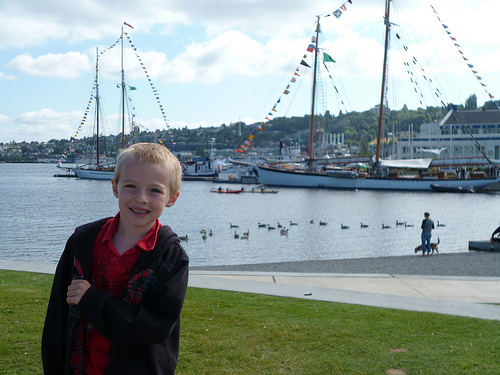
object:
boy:
[41, 142, 190, 375]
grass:
[0, 267, 500, 374]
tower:
[237, 115, 244, 137]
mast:
[376, 0, 391, 178]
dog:
[414, 236, 441, 256]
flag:
[124, 21, 134, 29]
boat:
[55, 21, 228, 181]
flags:
[332, 8, 343, 19]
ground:
[0, 250, 500, 375]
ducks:
[310, 219, 315, 224]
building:
[397, 105, 498, 162]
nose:
[133, 188, 149, 204]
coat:
[40, 216, 190, 375]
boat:
[429, 183, 477, 193]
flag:
[323, 52, 337, 63]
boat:
[228, 0, 500, 190]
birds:
[437, 220, 447, 227]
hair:
[112, 141, 182, 198]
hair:
[424, 211, 431, 218]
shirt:
[84, 210, 164, 375]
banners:
[300, 59, 312, 68]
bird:
[234, 230, 240, 238]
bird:
[319, 220, 328, 226]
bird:
[381, 223, 391, 228]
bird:
[229, 222, 239, 227]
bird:
[202, 231, 208, 239]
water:
[0, 162, 500, 267]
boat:
[210, 189, 242, 194]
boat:
[241, 189, 279, 193]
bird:
[319, 219, 329, 225]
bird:
[359, 221, 369, 228]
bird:
[257, 221, 267, 227]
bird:
[401, 220, 415, 230]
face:
[119, 160, 170, 227]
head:
[111, 142, 183, 227]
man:
[420, 211, 435, 256]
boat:
[223, 14, 374, 169]